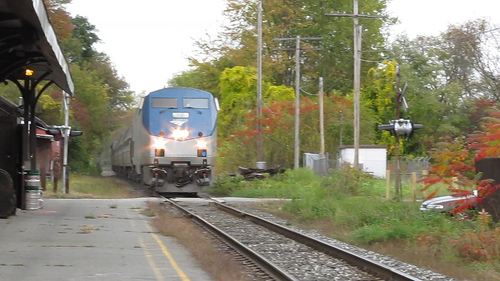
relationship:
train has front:
[97, 83, 228, 193] [152, 83, 219, 191]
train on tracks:
[97, 83, 228, 193] [168, 197, 404, 277]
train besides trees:
[97, 83, 228, 193] [221, 8, 386, 111]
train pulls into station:
[97, 83, 228, 193] [9, 3, 83, 218]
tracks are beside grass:
[168, 197, 404, 277] [260, 178, 451, 237]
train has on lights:
[97, 83, 228, 193] [147, 127, 212, 155]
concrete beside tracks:
[29, 200, 153, 275] [168, 197, 404, 277]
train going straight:
[97, 83, 228, 193] [233, 221, 255, 240]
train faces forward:
[97, 83, 228, 193] [258, 231, 283, 249]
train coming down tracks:
[97, 83, 228, 193] [168, 197, 404, 277]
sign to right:
[381, 79, 414, 121] [339, 141, 372, 153]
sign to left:
[47, 95, 81, 115] [83, 120, 100, 125]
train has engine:
[97, 83, 228, 193] [161, 169, 206, 186]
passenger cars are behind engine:
[110, 141, 130, 173] [161, 169, 206, 186]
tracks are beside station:
[168, 197, 404, 277] [9, 3, 83, 218]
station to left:
[9, 3, 83, 218] [83, 120, 100, 125]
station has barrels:
[9, 3, 83, 218] [20, 166, 46, 209]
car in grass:
[415, 191, 478, 215] [260, 178, 451, 237]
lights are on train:
[147, 127, 212, 155] [97, 83, 228, 193]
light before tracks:
[370, 115, 424, 140] [168, 197, 404, 277]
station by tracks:
[9, 3, 83, 218] [168, 197, 404, 277]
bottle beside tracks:
[37, 183, 47, 206] [168, 197, 404, 277]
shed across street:
[335, 140, 386, 196] [59, 196, 295, 204]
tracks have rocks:
[168, 197, 404, 277] [247, 224, 291, 246]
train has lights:
[97, 83, 228, 193] [147, 127, 212, 155]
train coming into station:
[97, 83, 228, 193] [9, 3, 83, 218]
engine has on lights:
[161, 169, 206, 186] [147, 127, 212, 155]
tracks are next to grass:
[168, 197, 404, 277] [260, 178, 451, 237]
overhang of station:
[0, 0, 75, 104] [9, 3, 83, 218]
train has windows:
[97, 83, 228, 193] [151, 96, 214, 112]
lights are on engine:
[147, 127, 212, 155] [161, 169, 206, 186]